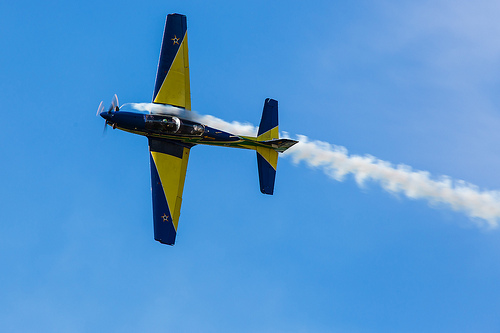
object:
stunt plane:
[96, 10, 297, 247]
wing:
[152, 11, 192, 111]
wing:
[145, 135, 191, 247]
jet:
[96, 10, 298, 250]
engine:
[110, 104, 256, 153]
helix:
[94, 102, 109, 114]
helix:
[105, 94, 119, 112]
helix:
[100, 111, 110, 133]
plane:
[94, 10, 293, 245]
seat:
[152, 114, 177, 132]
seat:
[180, 116, 204, 137]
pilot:
[157, 117, 168, 125]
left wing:
[146, 135, 193, 245]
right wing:
[150, 10, 190, 105]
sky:
[1, 1, 484, 331]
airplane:
[96, 11, 299, 246]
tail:
[255, 96, 299, 196]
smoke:
[119, 100, 484, 235]